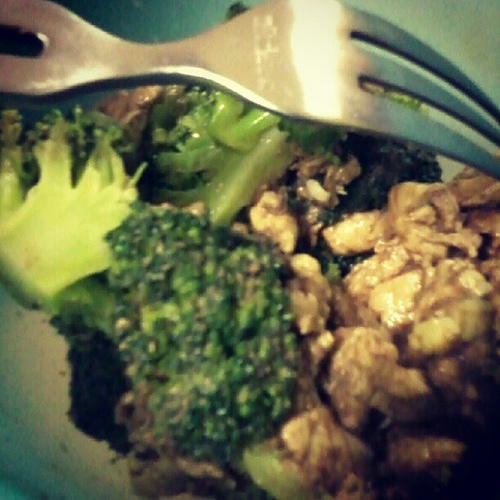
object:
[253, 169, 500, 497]
meat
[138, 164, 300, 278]
food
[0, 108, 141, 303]
broccoli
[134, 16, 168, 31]
bowl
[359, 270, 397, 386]
chicken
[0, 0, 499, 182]
fork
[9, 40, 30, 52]
shadow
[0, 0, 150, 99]
handle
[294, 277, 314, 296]
sauce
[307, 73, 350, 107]
reflection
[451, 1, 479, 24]
wall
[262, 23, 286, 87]
writing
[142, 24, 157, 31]
plate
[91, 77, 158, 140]
onion